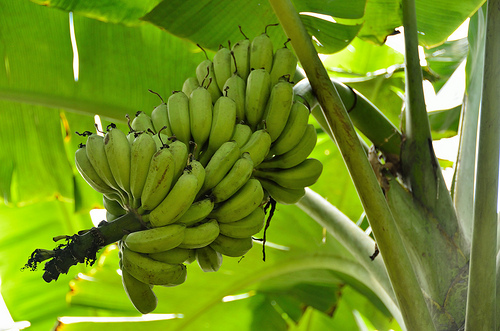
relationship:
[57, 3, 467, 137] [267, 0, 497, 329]
leaves of tree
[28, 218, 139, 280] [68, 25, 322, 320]
stem on bananas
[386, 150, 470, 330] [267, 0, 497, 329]
trunk of tree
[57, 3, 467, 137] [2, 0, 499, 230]
leaves in background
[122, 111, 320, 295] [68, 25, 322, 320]
bottom of bananas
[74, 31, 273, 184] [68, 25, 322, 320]
top of bananas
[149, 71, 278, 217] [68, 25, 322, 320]
middle of bananas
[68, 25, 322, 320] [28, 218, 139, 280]
bananas on stem